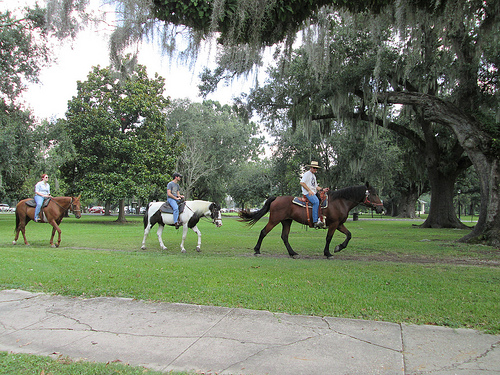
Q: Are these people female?
A: No, they are both male and female.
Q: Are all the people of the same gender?
A: No, they are both male and female.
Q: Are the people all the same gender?
A: No, they are both male and female.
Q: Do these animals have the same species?
A: Yes, all the animals are horses.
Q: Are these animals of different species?
A: No, all the animals are horses.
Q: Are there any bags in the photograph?
A: No, there are no bags.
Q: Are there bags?
A: No, there are no bags.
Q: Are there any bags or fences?
A: No, there are no bags or fences.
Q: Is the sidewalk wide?
A: Yes, the sidewalk is wide.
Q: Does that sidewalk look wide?
A: Yes, the sidewalk is wide.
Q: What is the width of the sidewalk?
A: The sidewalk is wide.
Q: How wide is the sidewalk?
A: The sidewalk is wide.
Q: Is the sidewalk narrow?
A: No, the sidewalk is wide.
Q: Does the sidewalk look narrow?
A: No, the sidewalk is wide.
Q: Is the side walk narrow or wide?
A: The side walk is wide.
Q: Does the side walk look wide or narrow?
A: The side walk is wide.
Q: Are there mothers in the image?
A: No, there are no mothers.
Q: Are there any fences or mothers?
A: No, there are no mothers or fences.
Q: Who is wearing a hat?
A: The man is wearing a hat.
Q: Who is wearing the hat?
A: The man is wearing a hat.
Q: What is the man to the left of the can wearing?
A: The man is wearing a hat.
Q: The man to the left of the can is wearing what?
A: The man is wearing a hat.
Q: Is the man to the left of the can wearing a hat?
A: Yes, the man is wearing a hat.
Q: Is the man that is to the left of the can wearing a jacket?
A: No, the man is wearing a hat.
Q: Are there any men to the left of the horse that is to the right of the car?
A: No, the man is to the right of the horse.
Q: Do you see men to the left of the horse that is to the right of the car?
A: No, the man is to the right of the horse.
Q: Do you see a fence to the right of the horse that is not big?
A: No, there is a man to the right of the horse.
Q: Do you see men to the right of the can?
A: No, the man is to the left of the can.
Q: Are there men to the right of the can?
A: No, the man is to the left of the can.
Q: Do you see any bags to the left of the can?
A: No, there is a man to the left of the can.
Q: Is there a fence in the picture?
A: No, there are no fences.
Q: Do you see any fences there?
A: No, there are no fences.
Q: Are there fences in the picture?
A: No, there are no fences.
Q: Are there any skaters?
A: No, there are no skaters.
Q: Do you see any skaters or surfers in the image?
A: No, there are no skaters or surfers.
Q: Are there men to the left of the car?
A: No, the man is to the right of the car.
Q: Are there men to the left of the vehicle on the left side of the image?
A: No, the man is to the right of the car.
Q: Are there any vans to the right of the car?
A: No, there is a man to the right of the car.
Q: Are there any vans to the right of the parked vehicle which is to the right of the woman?
A: No, there is a man to the right of the car.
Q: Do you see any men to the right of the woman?
A: Yes, there is a man to the right of the woman.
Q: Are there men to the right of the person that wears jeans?
A: Yes, there is a man to the right of the woman.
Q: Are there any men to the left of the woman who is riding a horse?
A: No, the man is to the right of the woman.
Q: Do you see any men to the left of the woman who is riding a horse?
A: No, the man is to the right of the woman.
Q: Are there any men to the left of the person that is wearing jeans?
A: No, the man is to the right of the woman.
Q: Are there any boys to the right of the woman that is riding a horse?
A: No, there is a man to the right of the woman.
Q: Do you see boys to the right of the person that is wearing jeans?
A: No, there is a man to the right of the woman.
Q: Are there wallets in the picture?
A: No, there are no wallets.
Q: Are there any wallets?
A: No, there are no wallets.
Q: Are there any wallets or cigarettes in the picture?
A: No, there are no wallets or cigarettes.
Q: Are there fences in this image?
A: No, there are no fences.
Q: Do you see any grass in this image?
A: Yes, there is grass.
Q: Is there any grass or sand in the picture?
A: Yes, there is grass.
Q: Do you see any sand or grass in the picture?
A: Yes, there is grass.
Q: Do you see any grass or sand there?
A: Yes, there is grass.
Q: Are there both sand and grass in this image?
A: No, there is grass but no sand.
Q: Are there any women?
A: Yes, there is a woman.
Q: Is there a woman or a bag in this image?
A: Yes, there is a woman.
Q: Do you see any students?
A: No, there are no students.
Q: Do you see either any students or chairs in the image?
A: No, there are no students or chairs.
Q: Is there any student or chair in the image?
A: No, there are no students or chairs.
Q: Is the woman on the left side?
A: Yes, the woman is on the left of the image.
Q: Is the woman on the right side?
A: No, the woman is on the left of the image.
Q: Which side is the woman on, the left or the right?
A: The woman is on the left of the image.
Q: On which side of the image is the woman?
A: The woman is on the left of the image.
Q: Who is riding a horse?
A: The woman is riding a horse.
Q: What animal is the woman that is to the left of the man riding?
A: The woman is riding a horse.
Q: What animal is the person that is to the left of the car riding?
A: The woman is riding a horse.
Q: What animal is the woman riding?
A: The woman is riding a horse.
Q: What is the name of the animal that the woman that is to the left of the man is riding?
A: The animal is a horse.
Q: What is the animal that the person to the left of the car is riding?
A: The animal is a horse.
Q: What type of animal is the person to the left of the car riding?
A: The woman is riding a horse.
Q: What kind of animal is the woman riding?
A: The woman is riding a horse.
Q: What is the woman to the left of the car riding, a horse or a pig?
A: The woman is riding a horse.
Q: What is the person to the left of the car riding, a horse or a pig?
A: The woman is riding a horse.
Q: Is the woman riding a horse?
A: Yes, the woman is riding a horse.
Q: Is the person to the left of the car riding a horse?
A: Yes, the woman is riding a horse.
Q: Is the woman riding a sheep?
A: No, the woman is riding a horse.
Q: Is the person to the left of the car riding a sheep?
A: No, the woman is riding a horse.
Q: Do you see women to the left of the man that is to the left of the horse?
A: Yes, there is a woman to the left of the man.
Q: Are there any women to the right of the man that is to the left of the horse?
A: No, the woman is to the left of the man.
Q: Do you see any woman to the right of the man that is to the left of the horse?
A: No, the woman is to the left of the man.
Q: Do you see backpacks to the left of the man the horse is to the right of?
A: No, there is a woman to the left of the man.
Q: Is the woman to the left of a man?
A: Yes, the woman is to the left of a man.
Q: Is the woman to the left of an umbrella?
A: No, the woman is to the left of a man.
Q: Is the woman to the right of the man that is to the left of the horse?
A: No, the woman is to the left of the man.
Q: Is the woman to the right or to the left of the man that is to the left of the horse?
A: The woman is to the left of the man.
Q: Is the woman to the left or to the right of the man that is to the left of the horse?
A: The woman is to the left of the man.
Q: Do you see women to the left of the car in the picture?
A: Yes, there is a woman to the left of the car.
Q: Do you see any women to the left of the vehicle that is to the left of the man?
A: Yes, there is a woman to the left of the car.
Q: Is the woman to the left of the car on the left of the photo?
A: Yes, the woman is to the left of the car.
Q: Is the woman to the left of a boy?
A: No, the woman is to the left of the car.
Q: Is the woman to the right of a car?
A: No, the woman is to the left of a car.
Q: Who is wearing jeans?
A: The woman is wearing jeans.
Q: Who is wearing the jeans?
A: The woman is wearing jeans.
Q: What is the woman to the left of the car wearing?
A: The woman is wearing jeans.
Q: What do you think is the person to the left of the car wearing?
A: The woman is wearing jeans.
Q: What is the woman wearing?
A: The woman is wearing jeans.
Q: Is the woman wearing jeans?
A: Yes, the woman is wearing jeans.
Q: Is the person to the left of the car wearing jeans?
A: Yes, the woman is wearing jeans.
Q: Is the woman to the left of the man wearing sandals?
A: No, the woman is wearing jeans.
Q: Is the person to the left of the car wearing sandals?
A: No, the woman is wearing jeans.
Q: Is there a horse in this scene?
A: Yes, there is a horse.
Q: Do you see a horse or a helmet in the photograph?
A: Yes, there is a horse.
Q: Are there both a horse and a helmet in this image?
A: No, there is a horse but no helmets.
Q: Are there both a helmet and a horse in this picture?
A: No, there is a horse but no helmets.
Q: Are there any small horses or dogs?
A: Yes, there is a small horse.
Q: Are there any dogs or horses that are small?
A: Yes, the horse is small.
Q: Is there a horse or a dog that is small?
A: Yes, the horse is small.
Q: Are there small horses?
A: Yes, there is a small horse.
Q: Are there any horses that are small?
A: Yes, there is a horse that is small.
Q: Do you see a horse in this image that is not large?
A: Yes, there is a small horse.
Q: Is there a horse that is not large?
A: Yes, there is a small horse.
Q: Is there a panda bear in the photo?
A: No, there are no panda bears.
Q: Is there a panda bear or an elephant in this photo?
A: No, there are no panda bears or elephants.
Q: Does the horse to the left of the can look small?
A: Yes, the horse is small.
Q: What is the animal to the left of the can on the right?
A: The animal is a horse.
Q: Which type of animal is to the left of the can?
A: The animal is a horse.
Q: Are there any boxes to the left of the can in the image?
A: No, there is a horse to the left of the can.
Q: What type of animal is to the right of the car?
A: The animal is a horse.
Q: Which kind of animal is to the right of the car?
A: The animal is a horse.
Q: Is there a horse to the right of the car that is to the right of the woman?
A: Yes, there is a horse to the right of the car.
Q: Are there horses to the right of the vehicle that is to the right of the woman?
A: Yes, there is a horse to the right of the car.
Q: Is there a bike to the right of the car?
A: No, there is a horse to the right of the car.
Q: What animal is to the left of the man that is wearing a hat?
A: The animal is a horse.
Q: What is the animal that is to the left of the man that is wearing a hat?
A: The animal is a horse.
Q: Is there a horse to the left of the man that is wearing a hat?
A: Yes, there is a horse to the left of the man.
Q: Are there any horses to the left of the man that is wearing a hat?
A: Yes, there is a horse to the left of the man.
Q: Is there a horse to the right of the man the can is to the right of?
A: No, the horse is to the left of the man.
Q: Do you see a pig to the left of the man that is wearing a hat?
A: No, there is a horse to the left of the man.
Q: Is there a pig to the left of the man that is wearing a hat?
A: No, there is a horse to the left of the man.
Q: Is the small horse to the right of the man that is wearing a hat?
A: No, the horse is to the left of the man.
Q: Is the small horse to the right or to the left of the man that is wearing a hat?
A: The horse is to the left of the man.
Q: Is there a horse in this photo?
A: Yes, there is a horse.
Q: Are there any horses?
A: Yes, there is a horse.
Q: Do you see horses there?
A: Yes, there is a horse.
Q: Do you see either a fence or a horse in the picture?
A: Yes, there is a horse.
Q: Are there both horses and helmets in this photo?
A: No, there is a horse but no helmets.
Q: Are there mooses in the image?
A: No, there are no mooses.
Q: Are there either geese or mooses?
A: No, there are no mooses or geese.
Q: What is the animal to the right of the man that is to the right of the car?
A: The animal is a horse.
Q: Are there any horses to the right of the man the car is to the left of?
A: Yes, there is a horse to the right of the man.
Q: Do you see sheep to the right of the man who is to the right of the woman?
A: No, there is a horse to the right of the man.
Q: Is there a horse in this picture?
A: Yes, there is a horse.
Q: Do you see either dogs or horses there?
A: Yes, there is a horse.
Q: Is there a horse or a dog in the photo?
A: Yes, there is a horse.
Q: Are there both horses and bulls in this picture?
A: No, there is a horse but no bulls.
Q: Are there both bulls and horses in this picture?
A: No, there is a horse but no bulls.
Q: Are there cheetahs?
A: No, there are no cheetahs.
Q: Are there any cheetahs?
A: No, there are no cheetahs.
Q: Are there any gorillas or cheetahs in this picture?
A: No, there are no cheetahs or gorillas.